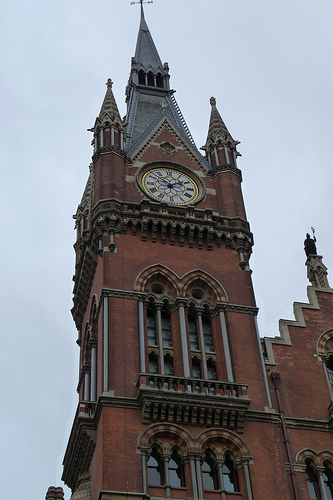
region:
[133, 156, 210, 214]
a large clock on a building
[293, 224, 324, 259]
a roof top statue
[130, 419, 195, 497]
window with an arch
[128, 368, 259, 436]
a ledge on the edge of a building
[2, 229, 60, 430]
a foggy sky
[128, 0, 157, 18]
a cross at the top of a building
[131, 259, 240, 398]
a large set of windows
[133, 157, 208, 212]
a large clock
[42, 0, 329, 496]
an extremely large building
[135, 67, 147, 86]
an opening in the tower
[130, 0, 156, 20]
a weather vane on top of a Church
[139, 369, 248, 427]
a stone carved railing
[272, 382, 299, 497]
a rusty metal drain pipe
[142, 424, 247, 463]
ornately carved arched awnings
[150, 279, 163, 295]
a circular window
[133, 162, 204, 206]
a large clock on top of the church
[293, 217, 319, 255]
a black statued on the roof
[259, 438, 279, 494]
red bricks in the building wall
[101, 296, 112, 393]
a gray column on the church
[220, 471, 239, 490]
light reflecting in the window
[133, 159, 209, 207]
a clock is on the tower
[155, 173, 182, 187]
the dials are black in color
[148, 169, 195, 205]
the numbers are roman numerals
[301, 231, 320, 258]
a statute is on top of the building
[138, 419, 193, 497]
an arched window is on the tower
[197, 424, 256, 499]
an arched window is on the tower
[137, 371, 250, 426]
a balcony is on the tower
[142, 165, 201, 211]
the clock has a goldem rim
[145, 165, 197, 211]
the clockface is white in color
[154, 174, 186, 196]
a golden circle is inside the clock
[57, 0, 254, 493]
very ornate clock tower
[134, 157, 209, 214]
large white clock with gold accents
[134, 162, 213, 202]
white clock with black roman numerals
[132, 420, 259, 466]
striped arches over windows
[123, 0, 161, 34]
weather vane at the top of clock tower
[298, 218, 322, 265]
statue on top of building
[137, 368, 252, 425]
small balcony below window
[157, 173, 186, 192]
black flower design on front of clock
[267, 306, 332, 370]
chipping paint on building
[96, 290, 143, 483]
building painted dark red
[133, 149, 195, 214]
black and white clock in tower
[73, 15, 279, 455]
brick clock tower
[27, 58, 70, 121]
white clouds in blue sky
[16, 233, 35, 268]
white clouds in blue sky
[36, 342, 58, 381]
white clouds in blue sky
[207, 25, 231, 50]
white clouds in blue sky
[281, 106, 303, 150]
white clouds in blue sky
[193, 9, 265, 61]
white clouds in blue sky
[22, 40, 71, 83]
white clouds in blue sky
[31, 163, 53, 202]
white clouds in blue sky